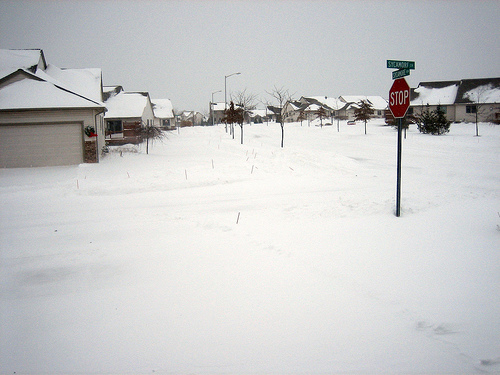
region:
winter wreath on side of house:
[77, 121, 103, 146]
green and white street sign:
[380, 55, 434, 78]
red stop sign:
[378, 76, 420, 255]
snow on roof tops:
[214, 71, 404, 137]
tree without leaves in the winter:
[259, 83, 291, 149]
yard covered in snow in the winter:
[0, 45, 201, 276]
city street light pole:
[212, 63, 245, 137]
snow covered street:
[235, 124, 478, 211]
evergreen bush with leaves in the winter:
[419, 104, 464, 143]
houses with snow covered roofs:
[6, 36, 177, 142]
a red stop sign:
[386, 77, 411, 119]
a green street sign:
[386, 57, 418, 72]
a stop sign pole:
[391, 117, 408, 218]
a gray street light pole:
[218, 69, 243, 124]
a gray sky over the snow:
[1, 0, 499, 122]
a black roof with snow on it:
[453, 79, 499, 103]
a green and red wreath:
[83, 124, 98, 140]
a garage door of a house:
[1, 122, 85, 171]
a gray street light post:
[207, 88, 222, 127]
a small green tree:
[351, 99, 374, 137]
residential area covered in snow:
[40, 28, 470, 198]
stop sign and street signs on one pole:
[361, 37, 421, 214]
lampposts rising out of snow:
[200, 55, 247, 132]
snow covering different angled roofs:
[15, 46, 145, 121]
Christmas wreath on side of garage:
[62, 105, 112, 162]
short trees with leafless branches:
[215, 85, 310, 156]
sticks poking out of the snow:
[60, 140, 290, 230]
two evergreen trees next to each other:
[415, 95, 465, 137]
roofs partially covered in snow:
[411, 75, 496, 105]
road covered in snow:
[20, 52, 411, 297]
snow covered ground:
[62, 169, 326, 306]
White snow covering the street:
[95, 169, 395, 311]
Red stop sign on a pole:
[381, 80, 436, 215]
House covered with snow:
[11, 66, 131, 166]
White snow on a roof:
[2, 45, 107, 129]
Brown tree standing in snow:
[259, 81, 313, 166]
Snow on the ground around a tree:
[254, 125, 337, 162]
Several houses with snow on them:
[274, 80, 493, 124]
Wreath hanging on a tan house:
[78, 118, 105, 139]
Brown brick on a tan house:
[81, 137, 106, 169]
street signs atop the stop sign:
[386, 56, 417, 78]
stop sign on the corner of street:
[389, 78, 424, 219]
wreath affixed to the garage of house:
[83, 123, 98, 138]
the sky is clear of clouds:
[0, 0, 498, 108]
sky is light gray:
[6, 0, 498, 132]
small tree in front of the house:
[139, 122, 164, 154]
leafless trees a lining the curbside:
[260, 99, 497, 134]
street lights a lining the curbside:
[206, 66, 242, 131]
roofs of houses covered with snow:
[0, 49, 499, 117]